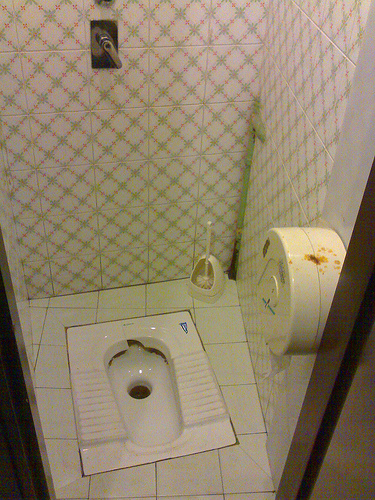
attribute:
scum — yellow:
[299, 241, 346, 281]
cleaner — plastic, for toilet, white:
[188, 220, 224, 302]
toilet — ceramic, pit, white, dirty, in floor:
[63, 310, 237, 477]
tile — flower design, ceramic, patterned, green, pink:
[2, 1, 372, 490]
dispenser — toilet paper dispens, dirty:
[256, 227, 348, 355]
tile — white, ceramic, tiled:
[17, 276, 274, 499]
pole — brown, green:
[228, 97, 261, 283]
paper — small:
[268, 353, 293, 376]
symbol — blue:
[181, 321, 190, 335]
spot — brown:
[148, 365, 158, 377]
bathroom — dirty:
[0, 0, 373, 499]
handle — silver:
[93, 17, 122, 72]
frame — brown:
[274, 154, 375, 499]